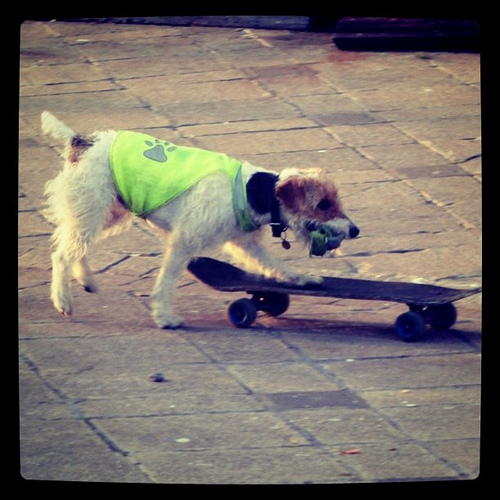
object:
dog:
[37, 107, 358, 332]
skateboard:
[185, 255, 475, 341]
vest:
[107, 129, 241, 216]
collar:
[263, 173, 284, 233]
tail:
[39, 108, 79, 159]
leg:
[49, 179, 114, 303]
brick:
[84, 407, 313, 456]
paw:
[152, 305, 184, 329]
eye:
[315, 197, 334, 211]